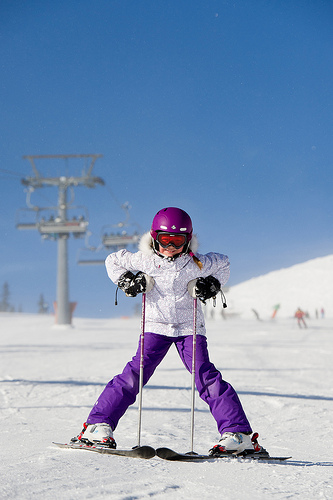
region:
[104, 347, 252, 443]
These are snowpants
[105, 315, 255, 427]
The snowpants are purple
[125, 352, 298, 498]
These are two poles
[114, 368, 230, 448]
The poles are metal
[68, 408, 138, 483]
This is a picture of shoes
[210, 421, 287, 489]
These shoes are white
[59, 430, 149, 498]
These are skiis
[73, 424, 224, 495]
The skiis are black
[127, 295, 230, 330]
This is a light purple jacket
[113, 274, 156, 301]
These are black gloves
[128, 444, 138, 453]
part of a board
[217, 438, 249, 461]
edge of a shoe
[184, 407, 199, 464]
part of a hooker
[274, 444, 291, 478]
part of a board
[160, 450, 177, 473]
part of a board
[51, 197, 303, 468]
a girl is sking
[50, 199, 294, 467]
the girl on skis poses for a photo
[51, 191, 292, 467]
the girl is smiling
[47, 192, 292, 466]
the girl is stopping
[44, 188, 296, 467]
the girl holds ski poles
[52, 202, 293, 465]
the girl wears a purple helmet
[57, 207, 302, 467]
the girl wears purple ski pants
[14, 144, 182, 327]
a ski lift to the left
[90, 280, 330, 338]
people skiing in the background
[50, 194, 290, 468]
the girl is wearing goggles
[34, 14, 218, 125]
a clear blue sky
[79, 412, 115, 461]
white sport shoes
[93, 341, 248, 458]
a purple shiny pant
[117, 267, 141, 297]
a black glove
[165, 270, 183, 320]
a white jacket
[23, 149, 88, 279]
a large electric pole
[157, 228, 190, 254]
goggles with red lens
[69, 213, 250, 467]
a girl with her legs apart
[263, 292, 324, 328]
people skiing on the snow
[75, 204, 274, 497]
a girl standing on a skateboard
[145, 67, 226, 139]
sky above the people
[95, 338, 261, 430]
purple pants on the girl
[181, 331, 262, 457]
leg of the girl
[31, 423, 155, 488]
ski on the ground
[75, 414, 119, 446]
foot of the girl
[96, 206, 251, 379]
purple and white outfit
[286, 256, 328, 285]
snow in the background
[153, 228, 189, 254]
red goggles on the girl's face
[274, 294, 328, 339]
people in the background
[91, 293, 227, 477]
two ski poles